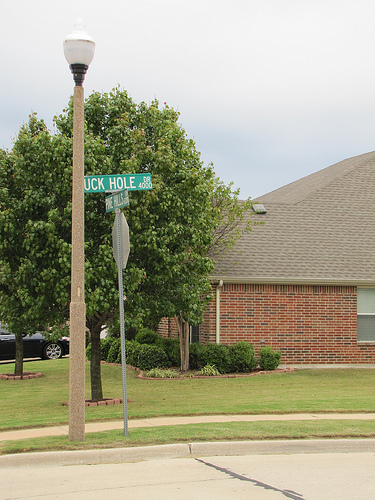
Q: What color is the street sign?
A: Green.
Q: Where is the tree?
A: Next to the house.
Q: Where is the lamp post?
A: Next to the street sign.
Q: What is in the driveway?
A: A car.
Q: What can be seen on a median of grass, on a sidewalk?
A: Three signs on a metal sign post.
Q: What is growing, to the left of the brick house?
A: A large tree with green foliage.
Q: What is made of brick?
A: A house.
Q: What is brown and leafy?
A: A tree, beside the house.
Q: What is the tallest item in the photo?
A: A light post.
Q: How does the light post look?
A: The light post is tall.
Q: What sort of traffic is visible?
A: The road is clear.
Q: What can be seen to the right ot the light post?
A: The back of stop sign, next to the street.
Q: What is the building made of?
A: Brick.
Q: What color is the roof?
A: Grey.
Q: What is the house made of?
A: Bricks.